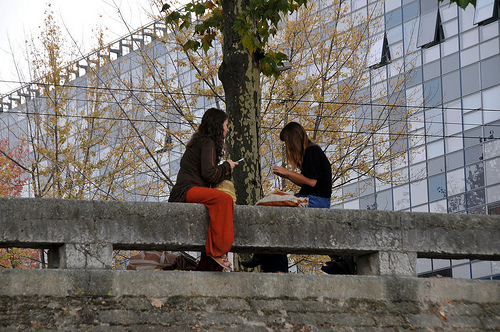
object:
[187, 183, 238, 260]
pants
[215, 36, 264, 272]
trunk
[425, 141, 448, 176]
windows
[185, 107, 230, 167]
hair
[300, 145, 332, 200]
shirt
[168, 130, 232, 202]
shirt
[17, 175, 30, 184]
leaves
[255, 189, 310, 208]
bag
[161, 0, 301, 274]
tree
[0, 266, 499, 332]
stone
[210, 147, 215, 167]
stripe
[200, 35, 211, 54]
leaves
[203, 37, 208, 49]
green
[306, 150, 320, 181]
short sleeves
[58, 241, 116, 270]
pillar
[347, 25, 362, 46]
leaves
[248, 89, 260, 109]
moss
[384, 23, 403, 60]
windows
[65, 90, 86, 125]
windows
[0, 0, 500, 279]
building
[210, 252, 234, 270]
foot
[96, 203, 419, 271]
wall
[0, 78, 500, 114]
wires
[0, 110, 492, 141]
electric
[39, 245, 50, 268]
trunk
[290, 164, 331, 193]
arm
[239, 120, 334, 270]
woman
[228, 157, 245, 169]
phone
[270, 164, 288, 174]
phone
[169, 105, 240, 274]
girl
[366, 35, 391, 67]
window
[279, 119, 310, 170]
hair